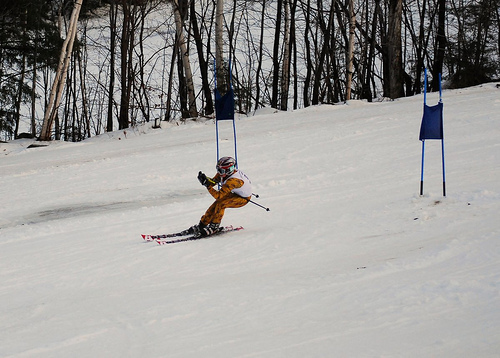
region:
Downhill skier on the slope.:
[110, 142, 302, 254]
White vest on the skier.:
[216, 165, 266, 210]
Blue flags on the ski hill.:
[188, 67, 481, 257]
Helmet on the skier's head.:
[209, 146, 250, 177]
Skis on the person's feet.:
[133, 217, 268, 254]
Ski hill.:
[10, 70, 499, 357]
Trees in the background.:
[1, 6, 493, 118]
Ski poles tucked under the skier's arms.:
[179, 155, 290, 230]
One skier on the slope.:
[78, 130, 340, 270]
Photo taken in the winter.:
[34, 1, 491, 351]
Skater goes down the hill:
[136, 144, 284, 255]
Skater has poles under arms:
[179, 142, 291, 242]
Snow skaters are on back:
[213, 176, 282, 221]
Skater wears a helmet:
[177, 144, 274, 250]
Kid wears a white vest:
[181, 142, 270, 245]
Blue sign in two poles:
[410, 55, 458, 210]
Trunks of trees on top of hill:
[17, 0, 492, 100]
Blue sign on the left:
[182, 73, 252, 160]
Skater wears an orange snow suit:
[177, 154, 269, 251]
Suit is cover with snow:
[0, 88, 499, 350]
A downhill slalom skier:
[123, 139, 275, 255]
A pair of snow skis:
[126, 205, 267, 260]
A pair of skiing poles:
[183, 164, 297, 224]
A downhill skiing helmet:
[196, 142, 254, 186]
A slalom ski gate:
[408, 70, 454, 212]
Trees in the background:
[6, 0, 498, 159]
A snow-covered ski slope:
[2, 39, 495, 354]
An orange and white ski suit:
[128, 147, 268, 256]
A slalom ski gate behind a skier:
[189, 74, 263, 184]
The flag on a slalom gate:
[401, 93, 457, 148]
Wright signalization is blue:
[401, 50, 452, 212]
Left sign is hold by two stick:
[194, 73, 245, 151]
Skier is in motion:
[181, 145, 266, 243]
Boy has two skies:
[136, 145, 286, 251]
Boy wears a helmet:
[170, 140, 277, 245]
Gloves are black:
[186, 160, 214, 190]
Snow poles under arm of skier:
[190, 168, 281, 213]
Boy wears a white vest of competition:
[178, 141, 273, 242]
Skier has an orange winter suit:
[176, 138, 281, 243]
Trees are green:
[4, 5, 59, 145]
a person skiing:
[71, 106, 316, 278]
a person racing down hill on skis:
[95, 55, 470, 296]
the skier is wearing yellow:
[118, 121, 369, 296]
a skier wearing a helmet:
[127, 148, 424, 302]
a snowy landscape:
[17, 56, 403, 356]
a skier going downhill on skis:
[38, 66, 457, 355]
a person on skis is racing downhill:
[106, 91, 343, 278]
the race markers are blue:
[189, 79, 462, 228]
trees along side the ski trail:
[30, 11, 467, 148]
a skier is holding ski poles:
[115, 136, 371, 286]